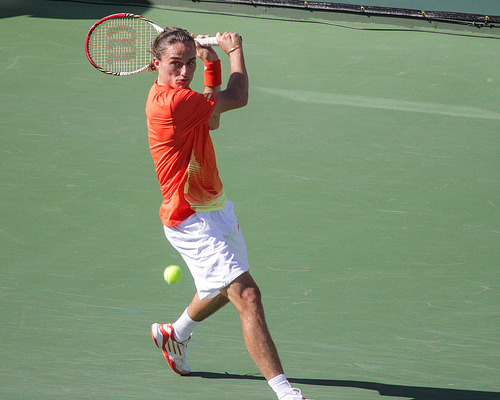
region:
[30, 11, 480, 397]
A person is on a tennis court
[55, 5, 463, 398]
A person is playing some tennis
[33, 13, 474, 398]
A person is getting some exercise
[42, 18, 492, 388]
A person is holding a tennis racket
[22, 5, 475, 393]
A person is hitting a tennis ball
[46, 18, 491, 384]
A person is wearing an orange shirt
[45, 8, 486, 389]
A person is wearing white shorts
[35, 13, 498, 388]
A person is having a great time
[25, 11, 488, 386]
A person is out in the sunshine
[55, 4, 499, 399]
A person is casting a shadow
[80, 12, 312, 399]
Man playing tennis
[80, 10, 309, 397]
Man hitting a tennis ball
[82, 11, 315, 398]
Man holding a tennis racket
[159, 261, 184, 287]
Yellow tennis ball in the air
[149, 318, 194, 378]
White and red tennis shoes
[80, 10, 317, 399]
Tennis player on a tennis court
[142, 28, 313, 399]
Man wearing an orange shirt and white shorts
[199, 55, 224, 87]
Thick orange wrist band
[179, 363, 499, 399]
Shadow of a man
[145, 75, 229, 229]
Orange and yellow shirt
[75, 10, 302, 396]
Female playing tennis on an outside court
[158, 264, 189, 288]
yellow tennis ball in flight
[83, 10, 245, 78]
red and white tennis racket held by tennis player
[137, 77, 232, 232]
orange shirt with yellow highlights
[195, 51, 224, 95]
orange wrist cuff worn by tennis player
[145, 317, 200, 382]
orange and white tennis shoe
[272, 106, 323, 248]
the tennis court is green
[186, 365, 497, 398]
shadow cast by the tennis player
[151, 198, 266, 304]
white shorts worn by tennis player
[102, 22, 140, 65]
letter 'w' logo on the tennis racket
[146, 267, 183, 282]
green tennis ball in air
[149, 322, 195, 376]
the man's left foot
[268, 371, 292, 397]
white sock on man's foot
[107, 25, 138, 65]
w on the net of racquet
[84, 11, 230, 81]
the tennis racket in man's hand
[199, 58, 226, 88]
wristband on man's wrist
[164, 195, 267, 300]
the man's white shorts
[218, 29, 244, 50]
the man's right hand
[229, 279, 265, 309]
the man's right knee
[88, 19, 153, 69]
white netting on tennis racquet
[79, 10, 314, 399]
this tennis player readies to hit the ball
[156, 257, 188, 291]
the tennis ball flying through midair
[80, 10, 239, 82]
the W means the tennis racquet is made by Wilson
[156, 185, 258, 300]
the tennis player wears white shorts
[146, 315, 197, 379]
the tennis player's shoes are trimmed in red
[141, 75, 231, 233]
the tennis player wears an orange top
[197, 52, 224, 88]
the tennis player wears an orange sweatband on the wrist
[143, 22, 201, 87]
the tennis player's hair pulled off the face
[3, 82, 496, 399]
tennis player playing on a clay court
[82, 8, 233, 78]
tennis racquet is red and white